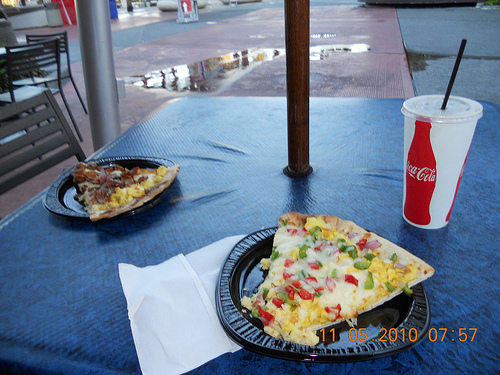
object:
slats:
[7, 39, 60, 71]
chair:
[1, 40, 86, 142]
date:
[318, 326, 425, 348]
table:
[0, 96, 497, 373]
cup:
[399, 96, 484, 230]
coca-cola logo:
[403, 119, 435, 225]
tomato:
[260, 301, 282, 332]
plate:
[45, 154, 180, 222]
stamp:
[312, 321, 480, 346]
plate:
[214, 220, 434, 360]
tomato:
[296, 286, 310, 298]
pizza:
[256, 208, 436, 335]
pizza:
[65, 160, 182, 221]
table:
[3, 2, 496, 374]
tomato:
[312, 241, 324, 258]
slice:
[71, 158, 179, 224]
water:
[110, 31, 369, 95]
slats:
[6, 73, 103, 204]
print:
[300, 311, 476, 353]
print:
[378, 327, 420, 342]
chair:
[26, 30, 86, 117]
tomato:
[268, 295, 291, 305]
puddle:
[120, 40, 372, 93]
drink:
[390, 85, 487, 235]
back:
[1, 84, 71, 176]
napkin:
[102, 225, 242, 372]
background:
[1, 14, 74, 94]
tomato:
[289, 271, 305, 298]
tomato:
[313, 277, 330, 296]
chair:
[3, 75, 85, 203]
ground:
[124, 16, 382, 107]